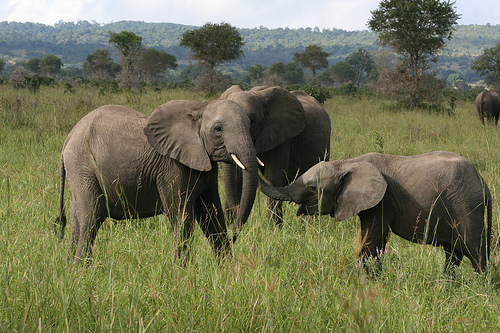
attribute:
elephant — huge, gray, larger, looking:
[56, 98, 264, 260]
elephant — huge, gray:
[219, 86, 331, 241]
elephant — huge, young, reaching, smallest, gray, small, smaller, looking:
[251, 150, 493, 272]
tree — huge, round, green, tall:
[366, 1, 462, 120]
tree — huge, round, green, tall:
[181, 20, 241, 96]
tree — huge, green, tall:
[106, 31, 142, 91]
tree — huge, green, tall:
[292, 44, 329, 80]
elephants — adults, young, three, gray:
[57, 84, 492, 275]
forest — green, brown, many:
[1, 1, 499, 98]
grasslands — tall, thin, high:
[1, 80, 499, 330]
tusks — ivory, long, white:
[231, 153, 265, 169]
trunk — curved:
[233, 153, 259, 226]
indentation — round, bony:
[85, 102, 102, 172]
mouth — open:
[290, 197, 306, 216]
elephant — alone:
[475, 89, 499, 126]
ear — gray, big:
[148, 99, 213, 171]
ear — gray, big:
[254, 88, 306, 152]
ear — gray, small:
[335, 161, 389, 222]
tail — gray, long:
[55, 133, 71, 254]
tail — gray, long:
[482, 181, 492, 262]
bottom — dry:
[386, 56, 448, 111]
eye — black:
[212, 123, 223, 133]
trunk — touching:
[256, 176, 301, 202]